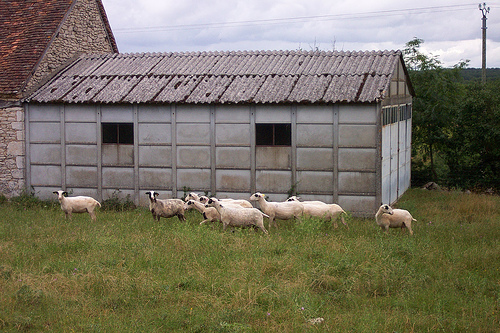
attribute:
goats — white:
[52, 179, 416, 235]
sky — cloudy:
[127, 23, 492, 77]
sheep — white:
[49, 183, 419, 245]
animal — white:
[368, 196, 425, 243]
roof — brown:
[1, 0, 120, 108]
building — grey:
[0, 1, 422, 234]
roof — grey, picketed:
[20, 44, 400, 101]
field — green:
[12, 207, 488, 313]